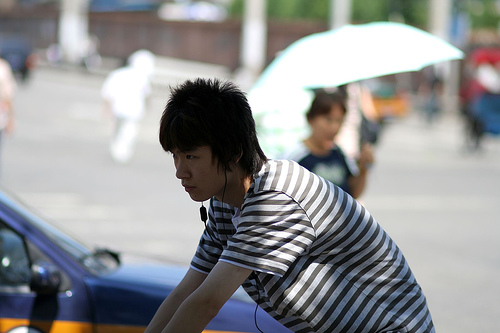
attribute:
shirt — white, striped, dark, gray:
[191, 158, 436, 333]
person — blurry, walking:
[278, 91, 375, 201]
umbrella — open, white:
[244, 21, 466, 93]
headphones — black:
[171, 86, 264, 332]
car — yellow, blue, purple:
[2, 195, 290, 331]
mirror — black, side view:
[30, 261, 63, 295]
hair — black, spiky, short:
[159, 77, 269, 176]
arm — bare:
[145, 198, 224, 324]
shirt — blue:
[274, 140, 359, 194]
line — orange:
[2, 316, 234, 332]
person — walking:
[100, 49, 160, 155]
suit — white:
[98, 68, 150, 152]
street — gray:
[2, 133, 498, 330]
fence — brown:
[0, 2, 328, 76]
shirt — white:
[101, 66, 150, 117]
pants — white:
[107, 111, 138, 160]